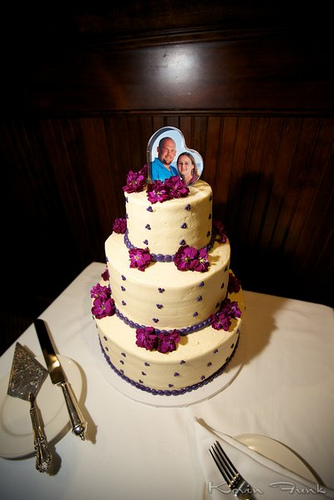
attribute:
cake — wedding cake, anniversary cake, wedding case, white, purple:
[90, 125, 249, 400]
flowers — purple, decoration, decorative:
[122, 167, 196, 204]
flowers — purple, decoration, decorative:
[108, 220, 230, 271]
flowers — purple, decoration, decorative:
[90, 283, 245, 352]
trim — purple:
[120, 233, 176, 264]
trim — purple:
[112, 308, 224, 334]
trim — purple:
[104, 370, 237, 397]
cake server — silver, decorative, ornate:
[5, 339, 58, 479]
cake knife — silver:
[33, 315, 88, 448]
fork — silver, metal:
[207, 441, 260, 498]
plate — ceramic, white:
[2, 350, 85, 461]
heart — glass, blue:
[144, 124, 210, 186]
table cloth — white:
[2, 256, 333, 497]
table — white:
[0, 242, 332, 496]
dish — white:
[1, 343, 93, 476]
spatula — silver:
[4, 337, 59, 475]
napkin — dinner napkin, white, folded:
[195, 431, 330, 497]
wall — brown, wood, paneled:
[2, 3, 328, 344]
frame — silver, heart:
[139, 127, 210, 184]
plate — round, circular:
[98, 354, 251, 411]